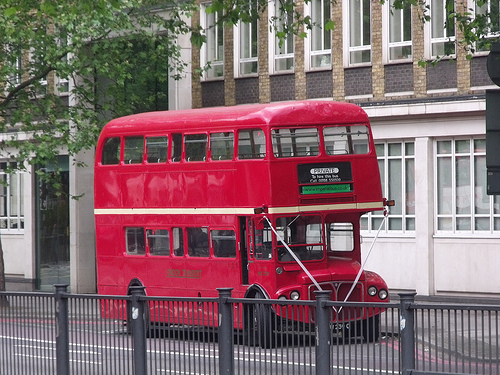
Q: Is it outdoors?
A: Yes, it is outdoors.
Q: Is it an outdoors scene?
A: Yes, it is outdoors.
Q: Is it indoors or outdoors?
A: It is outdoors.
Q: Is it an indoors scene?
A: No, it is outdoors.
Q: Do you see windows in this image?
A: Yes, there is a window.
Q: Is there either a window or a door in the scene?
A: Yes, there is a window.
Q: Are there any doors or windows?
A: Yes, there is a window.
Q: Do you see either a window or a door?
A: Yes, there is a window.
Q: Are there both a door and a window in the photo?
A: Yes, there are both a window and a door.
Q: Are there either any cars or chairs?
A: No, there are no cars or chairs.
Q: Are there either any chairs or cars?
A: No, there are no cars or chairs.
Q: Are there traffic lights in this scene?
A: No, there are no traffic lights.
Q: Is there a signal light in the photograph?
A: No, there are no traffic lights.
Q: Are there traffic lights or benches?
A: No, there are no traffic lights or benches.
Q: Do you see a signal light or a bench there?
A: No, there are no traffic lights or benches.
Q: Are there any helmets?
A: No, there are no helmets.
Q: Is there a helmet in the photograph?
A: No, there are no helmets.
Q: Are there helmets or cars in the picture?
A: No, there are no helmets or cars.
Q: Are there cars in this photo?
A: No, there are no cars.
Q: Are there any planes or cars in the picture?
A: No, there are no cars or planes.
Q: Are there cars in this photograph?
A: No, there are no cars.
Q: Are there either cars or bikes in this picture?
A: No, there are no cars or bikes.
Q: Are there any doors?
A: Yes, there is a door.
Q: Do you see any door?
A: Yes, there is a door.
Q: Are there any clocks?
A: No, there are no clocks.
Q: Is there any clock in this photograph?
A: No, there are no clocks.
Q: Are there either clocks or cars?
A: No, there are no clocks or cars.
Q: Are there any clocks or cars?
A: No, there are no cars or clocks.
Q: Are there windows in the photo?
A: Yes, there is a window.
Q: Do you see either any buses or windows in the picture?
A: Yes, there is a window.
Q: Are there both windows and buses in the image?
A: Yes, there are both a window and a bus.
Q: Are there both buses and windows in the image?
A: Yes, there are both a window and a bus.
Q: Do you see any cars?
A: No, there are no cars.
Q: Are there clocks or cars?
A: No, there are no cars or clocks.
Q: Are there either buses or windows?
A: Yes, there are windows.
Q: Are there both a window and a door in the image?
A: Yes, there are both a window and a door.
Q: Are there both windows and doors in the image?
A: Yes, there are both windows and a door.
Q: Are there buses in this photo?
A: Yes, there is a bus.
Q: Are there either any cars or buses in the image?
A: Yes, there is a bus.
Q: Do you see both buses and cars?
A: No, there is a bus but no cars.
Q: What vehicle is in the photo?
A: The vehicle is a bus.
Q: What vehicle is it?
A: The vehicle is a bus.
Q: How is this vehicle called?
A: That is a bus.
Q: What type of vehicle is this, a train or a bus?
A: That is a bus.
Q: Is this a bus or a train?
A: This is a bus.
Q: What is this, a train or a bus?
A: This is a bus.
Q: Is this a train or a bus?
A: This is a bus.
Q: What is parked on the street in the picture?
A: The bus is parked on the street.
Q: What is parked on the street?
A: The bus is parked on the street.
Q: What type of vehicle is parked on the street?
A: The vehicle is a bus.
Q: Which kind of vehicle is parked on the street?
A: The vehicle is a bus.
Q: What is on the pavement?
A: The bus is on the pavement.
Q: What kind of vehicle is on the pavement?
A: The vehicle is a bus.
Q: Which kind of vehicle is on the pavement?
A: The vehicle is a bus.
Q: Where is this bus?
A: The bus is on the pavement.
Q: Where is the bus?
A: The bus is on the pavement.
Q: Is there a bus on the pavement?
A: Yes, there is a bus on the pavement.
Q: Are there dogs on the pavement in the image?
A: No, there is a bus on the pavement.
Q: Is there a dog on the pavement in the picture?
A: No, there is a bus on the pavement.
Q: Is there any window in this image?
A: Yes, there is a window.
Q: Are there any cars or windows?
A: Yes, there is a window.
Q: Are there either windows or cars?
A: Yes, there is a window.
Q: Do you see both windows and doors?
A: Yes, there are both a window and doors.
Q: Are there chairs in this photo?
A: No, there are no chairs.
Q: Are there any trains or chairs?
A: No, there are no chairs or trains.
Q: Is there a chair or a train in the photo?
A: No, there are no chairs or trains.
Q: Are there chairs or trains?
A: No, there are no chairs or trains.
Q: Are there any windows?
A: Yes, there is a window.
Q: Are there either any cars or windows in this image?
A: Yes, there is a window.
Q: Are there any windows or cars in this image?
A: Yes, there is a window.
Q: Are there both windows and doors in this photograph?
A: Yes, there are both a window and a door.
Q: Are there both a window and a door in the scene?
A: Yes, there are both a window and a door.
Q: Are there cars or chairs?
A: No, there are no cars or chairs.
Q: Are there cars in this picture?
A: No, there are no cars.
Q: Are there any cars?
A: No, there are no cars.